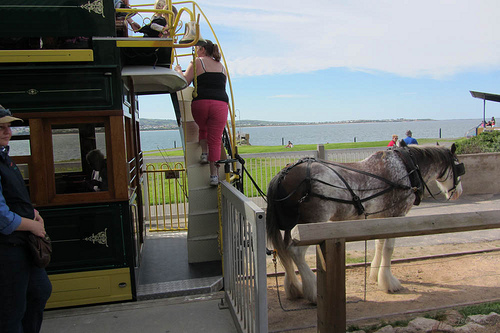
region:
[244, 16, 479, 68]
White clouds against blue sky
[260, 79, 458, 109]
Blue sky above water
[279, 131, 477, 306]
Brown and white horse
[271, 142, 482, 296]
Brown and white horse with blinders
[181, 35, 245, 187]
Woman climbing stairs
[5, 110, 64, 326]
Man standing and wearing black pants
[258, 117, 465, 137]
Blue calm water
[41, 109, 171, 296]
Red, brown and yellow building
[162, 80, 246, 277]
Woman climbing tan stairs of building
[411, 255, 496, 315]
Shadow of horse in brown dirt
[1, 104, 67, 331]
A person standing on a gray platform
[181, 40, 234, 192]
A woman climbing stairs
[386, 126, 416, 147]
Two people in the distance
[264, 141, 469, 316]
A horse standing behind a fence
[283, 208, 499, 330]
Part of a wooden fence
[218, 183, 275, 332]
A gray metal gate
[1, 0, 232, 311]
A large yellow,black and brown vehicle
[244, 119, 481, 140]
A large body of water in the distance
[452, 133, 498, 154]
Green bushes behind a wall on the right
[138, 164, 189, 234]
A yellow gate on the other side of the vehicle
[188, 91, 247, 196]
Woman is wearing pink pants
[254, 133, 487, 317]
A side view of a horse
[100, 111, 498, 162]
Large body of water is in the background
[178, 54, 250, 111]
Woman's tank top is black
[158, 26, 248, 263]
Woman is walking up the steps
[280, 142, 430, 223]
Horse has dark colored straps on its back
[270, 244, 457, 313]
Horse's feet are cream white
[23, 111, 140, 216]
Window has wood around it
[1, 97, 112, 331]
Person is in the foreground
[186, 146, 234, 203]
Woman is wearing white shoes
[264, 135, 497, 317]
Horse with blinders on.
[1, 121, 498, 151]
Water in the background.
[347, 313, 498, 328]
Stones on the ground.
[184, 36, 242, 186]
Woman in pink pants.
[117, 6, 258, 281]
Curved stairway on trolley.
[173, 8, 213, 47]
Bell at the top of the stairway.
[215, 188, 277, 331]
Metal fence between trolley and horse.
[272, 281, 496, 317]
Shadow of horse on ground.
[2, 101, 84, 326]
Bystander standing by the trolley.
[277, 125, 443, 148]
People in the background.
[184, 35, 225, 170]
Girl climbing the stairs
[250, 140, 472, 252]
A white and brown horse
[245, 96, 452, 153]
A view of the lake or ocean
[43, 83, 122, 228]
A window beneath the stairs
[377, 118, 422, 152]
People sitting outside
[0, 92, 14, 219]
A lady sitting down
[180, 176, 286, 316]
A silver railing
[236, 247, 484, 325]
Sand under where the horse is standing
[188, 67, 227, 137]
Girl has a black shirt on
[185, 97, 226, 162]
girl has pink pants on